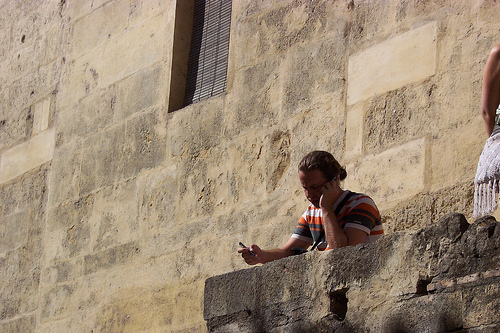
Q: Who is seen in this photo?
A: A man.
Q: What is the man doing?
A: Talking on a cellphone.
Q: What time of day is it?
A: Daytime.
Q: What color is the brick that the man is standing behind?
A: Gray.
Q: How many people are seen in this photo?
A: One.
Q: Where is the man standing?
A: On a ledge of a building.